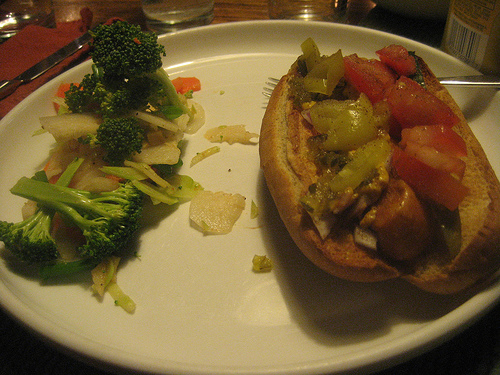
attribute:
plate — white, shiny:
[0, 16, 498, 375]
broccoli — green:
[5, 173, 148, 265]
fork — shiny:
[256, 68, 499, 112]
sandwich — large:
[255, 34, 499, 307]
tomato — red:
[376, 42, 419, 75]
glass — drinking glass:
[137, 1, 221, 35]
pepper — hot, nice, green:
[298, 33, 323, 71]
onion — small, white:
[351, 221, 380, 253]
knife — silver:
[0, 22, 108, 101]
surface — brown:
[210, 2, 270, 24]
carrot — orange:
[168, 73, 206, 96]